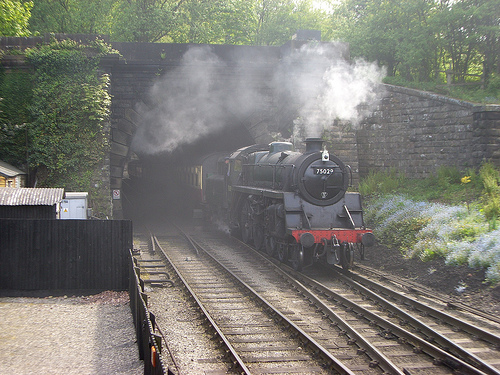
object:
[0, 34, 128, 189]
ivy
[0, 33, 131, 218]
brick wall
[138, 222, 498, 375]
track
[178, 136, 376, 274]
train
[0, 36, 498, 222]
overpath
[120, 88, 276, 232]
tunnel